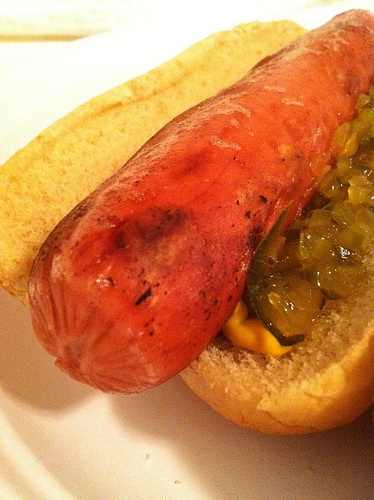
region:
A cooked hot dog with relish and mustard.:
[14, 17, 356, 449]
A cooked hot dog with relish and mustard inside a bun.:
[11, 12, 362, 478]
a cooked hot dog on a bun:
[1, 6, 373, 452]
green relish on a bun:
[249, 88, 372, 342]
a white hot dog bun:
[0, 12, 370, 439]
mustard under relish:
[218, 289, 306, 377]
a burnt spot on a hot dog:
[129, 280, 155, 308]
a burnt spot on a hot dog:
[255, 189, 272, 210]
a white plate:
[4, 282, 367, 496]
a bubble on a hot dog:
[206, 127, 247, 154]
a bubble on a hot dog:
[281, 90, 309, 108]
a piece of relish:
[245, 212, 325, 348]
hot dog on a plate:
[1, 3, 372, 497]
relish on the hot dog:
[238, 79, 372, 340]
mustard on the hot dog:
[221, 295, 295, 358]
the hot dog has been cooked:
[26, 0, 372, 395]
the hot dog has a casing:
[23, 1, 372, 402]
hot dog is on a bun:
[6, 8, 372, 470]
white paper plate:
[11, 286, 370, 498]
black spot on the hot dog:
[110, 190, 200, 281]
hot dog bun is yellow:
[4, 2, 371, 451]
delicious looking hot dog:
[3, 0, 371, 474]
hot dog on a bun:
[0, 9, 370, 438]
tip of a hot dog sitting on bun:
[26, 230, 201, 397]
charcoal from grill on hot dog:
[133, 286, 152, 305]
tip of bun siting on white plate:
[201, 356, 362, 436]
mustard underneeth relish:
[223, 303, 296, 359]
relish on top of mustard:
[243, 275, 326, 343]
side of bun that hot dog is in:
[0, 21, 281, 287]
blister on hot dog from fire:
[277, 142, 311, 183]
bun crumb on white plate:
[305, 467, 315, 472]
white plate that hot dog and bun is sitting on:
[27, 62, 78, 107]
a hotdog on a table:
[28, 48, 336, 440]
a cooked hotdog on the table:
[8, 72, 336, 474]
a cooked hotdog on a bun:
[85, 99, 302, 347]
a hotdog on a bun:
[48, 146, 367, 473]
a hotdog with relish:
[142, 95, 370, 415]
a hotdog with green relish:
[107, 100, 369, 429]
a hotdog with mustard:
[99, 88, 370, 397]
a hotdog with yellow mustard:
[56, 94, 361, 322]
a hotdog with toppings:
[72, 62, 367, 383]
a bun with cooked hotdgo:
[85, 133, 369, 391]